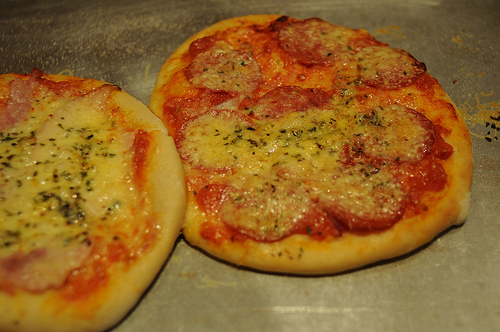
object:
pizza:
[145, 14, 477, 277]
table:
[0, 10, 498, 331]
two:
[0, 14, 477, 331]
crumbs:
[460, 74, 500, 110]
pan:
[186, 32, 385, 222]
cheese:
[177, 49, 427, 227]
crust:
[126, 66, 191, 224]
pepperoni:
[188, 46, 264, 93]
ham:
[7, 69, 140, 155]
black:
[483, 136, 492, 143]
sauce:
[430, 120, 443, 177]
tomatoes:
[193, 34, 236, 53]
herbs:
[25, 119, 106, 172]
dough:
[152, 112, 187, 258]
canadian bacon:
[305, 156, 401, 232]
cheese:
[182, 109, 270, 166]